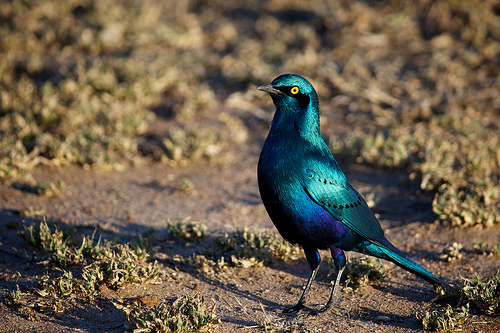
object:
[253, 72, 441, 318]
bird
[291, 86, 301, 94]
eye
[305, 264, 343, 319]
feet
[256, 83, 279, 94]
beak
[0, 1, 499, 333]
ground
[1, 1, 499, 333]
grass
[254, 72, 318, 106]
head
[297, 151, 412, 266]
wing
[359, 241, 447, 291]
tail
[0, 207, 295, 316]
shadow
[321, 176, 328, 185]
dots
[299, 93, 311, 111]
markings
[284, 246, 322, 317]
right leg